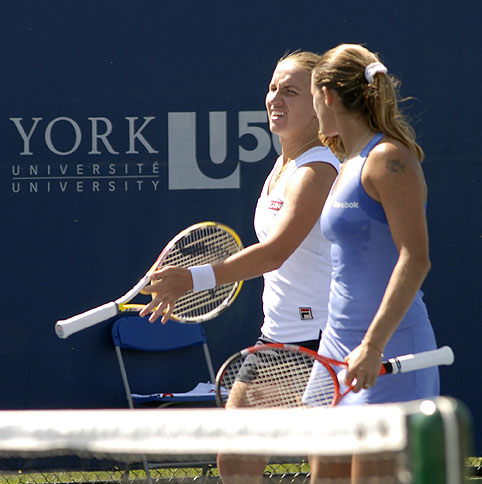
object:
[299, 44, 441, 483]
woman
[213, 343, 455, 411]
tennis racket